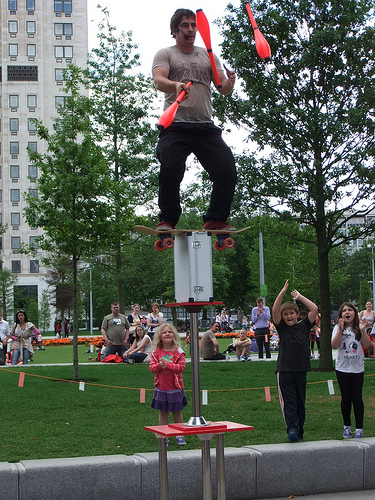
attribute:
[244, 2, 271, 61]
juggling pin — bright orange, in the air, red, black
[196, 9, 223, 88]
juggling pin — bright orange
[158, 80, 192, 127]
juggling pin — bright orange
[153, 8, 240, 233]
juggler — juggling pins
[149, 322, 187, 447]
girl — young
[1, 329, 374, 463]
grass — green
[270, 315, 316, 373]
shirt — black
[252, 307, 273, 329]
shirt — light purple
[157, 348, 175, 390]
shirt — pink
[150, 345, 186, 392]
jacket — pink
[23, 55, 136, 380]
tree — slim, deciduous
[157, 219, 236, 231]
shoes — red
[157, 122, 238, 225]
pants — black, long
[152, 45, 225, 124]
shirt — tan, brown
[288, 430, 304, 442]
shoes — black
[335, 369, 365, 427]
leggings — black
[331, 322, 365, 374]
shirt — white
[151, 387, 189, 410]
skirt — purple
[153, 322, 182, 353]
hair — blond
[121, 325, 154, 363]
woman — sitting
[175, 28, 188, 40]
microphone — black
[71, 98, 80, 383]
trunk — skinny, brown